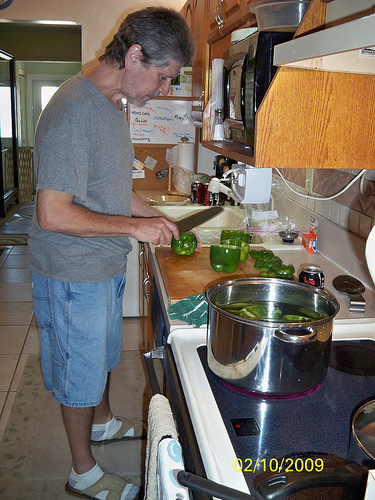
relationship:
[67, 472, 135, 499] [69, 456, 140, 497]
sandal covering sock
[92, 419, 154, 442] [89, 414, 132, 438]
sandal covering sock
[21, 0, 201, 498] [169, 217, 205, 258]
man cutting pepper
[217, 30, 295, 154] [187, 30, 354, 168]
microwave on shelf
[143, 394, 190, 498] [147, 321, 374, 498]
towel hanging on front of stove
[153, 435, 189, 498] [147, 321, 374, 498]
towel hanging on front of stove